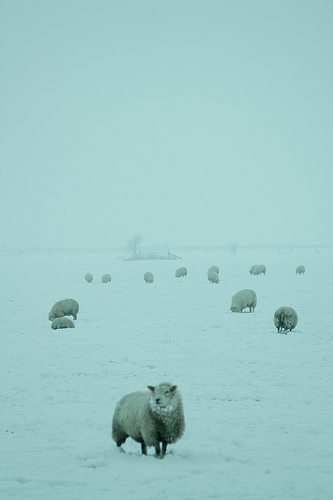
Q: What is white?
A: Snow.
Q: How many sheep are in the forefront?
A: One.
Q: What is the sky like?
A: Cloudy.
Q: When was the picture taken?
A: Daytime.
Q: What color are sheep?
A: White.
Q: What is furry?
A: The sheep.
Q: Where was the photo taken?
A: Farm pasture.